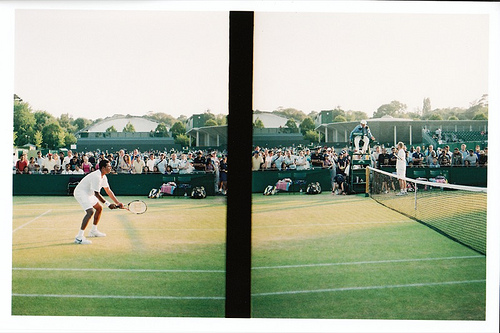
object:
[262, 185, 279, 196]
bags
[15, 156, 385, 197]
court side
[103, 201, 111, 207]
sweatband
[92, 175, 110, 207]
arm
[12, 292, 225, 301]
lines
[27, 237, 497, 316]
floor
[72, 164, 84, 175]
spectators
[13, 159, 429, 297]
game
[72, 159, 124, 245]
man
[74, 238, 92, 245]
shoes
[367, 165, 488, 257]
net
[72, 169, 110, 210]
white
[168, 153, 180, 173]
people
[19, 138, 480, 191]
audience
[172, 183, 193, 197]
bags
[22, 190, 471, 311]
ground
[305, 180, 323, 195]
bags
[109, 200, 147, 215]
tennis racket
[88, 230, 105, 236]
shoes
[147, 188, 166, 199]
bags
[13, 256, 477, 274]
line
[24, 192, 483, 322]
tennis court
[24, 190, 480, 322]
court floor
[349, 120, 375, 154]
referee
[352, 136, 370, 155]
chair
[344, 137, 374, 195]
referee stand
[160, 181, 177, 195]
bags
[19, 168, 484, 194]
sideline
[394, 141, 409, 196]
someone